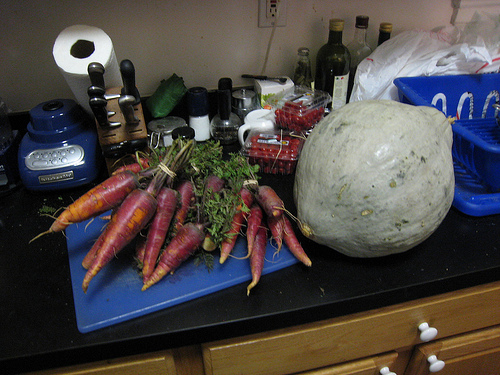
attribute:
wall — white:
[7, 0, 499, 114]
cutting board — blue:
[60, 171, 302, 330]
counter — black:
[5, 61, 498, 368]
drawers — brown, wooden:
[205, 289, 499, 373]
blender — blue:
[18, 96, 104, 195]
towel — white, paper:
[50, 20, 127, 122]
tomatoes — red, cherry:
[236, 81, 332, 180]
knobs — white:
[384, 321, 451, 373]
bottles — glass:
[288, 14, 396, 113]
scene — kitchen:
[5, 9, 498, 366]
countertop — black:
[12, 57, 496, 366]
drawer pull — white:
[419, 317, 438, 342]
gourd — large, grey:
[291, 101, 460, 258]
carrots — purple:
[27, 126, 319, 294]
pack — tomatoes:
[271, 82, 331, 134]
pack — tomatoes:
[239, 130, 302, 177]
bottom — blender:
[19, 93, 104, 196]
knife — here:
[90, 95, 114, 134]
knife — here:
[122, 93, 140, 133]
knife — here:
[114, 57, 145, 102]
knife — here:
[86, 63, 108, 93]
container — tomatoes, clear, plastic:
[268, 79, 335, 130]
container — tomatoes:
[236, 127, 304, 186]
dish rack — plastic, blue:
[394, 64, 499, 219]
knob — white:
[418, 325, 441, 343]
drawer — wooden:
[205, 289, 499, 369]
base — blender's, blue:
[16, 91, 94, 200]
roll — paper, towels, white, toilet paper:
[47, 14, 138, 111]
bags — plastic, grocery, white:
[347, 12, 498, 103]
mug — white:
[238, 106, 278, 146]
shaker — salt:
[187, 83, 214, 150]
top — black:
[186, 86, 211, 119]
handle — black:
[91, 96, 109, 127]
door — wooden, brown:
[91, 350, 180, 372]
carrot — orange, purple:
[82, 187, 158, 291]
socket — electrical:
[253, 5, 289, 31]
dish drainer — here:
[394, 72, 499, 217]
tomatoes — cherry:
[275, 98, 323, 129]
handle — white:
[425, 361, 449, 374]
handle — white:
[417, 326, 441, 343]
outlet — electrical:
[254, 4, 289, 29]